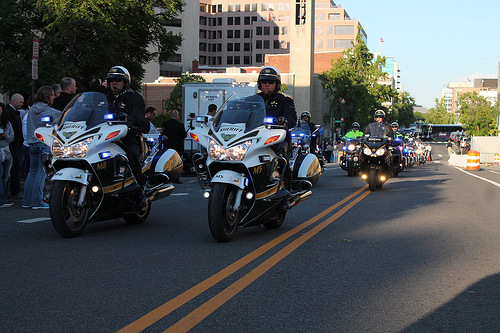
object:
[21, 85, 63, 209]
people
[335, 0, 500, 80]
sky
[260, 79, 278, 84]
eyeglasses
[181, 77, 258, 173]
ambulance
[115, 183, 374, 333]
line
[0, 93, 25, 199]
person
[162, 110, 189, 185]
person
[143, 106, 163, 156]
person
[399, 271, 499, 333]
shadow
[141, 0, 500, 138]
buildings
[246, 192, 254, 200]
light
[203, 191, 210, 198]
light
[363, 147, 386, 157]
light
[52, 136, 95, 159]
light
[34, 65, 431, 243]
motorcycle parade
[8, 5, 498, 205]
background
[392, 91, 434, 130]
trees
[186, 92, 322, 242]
bike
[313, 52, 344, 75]
red bricks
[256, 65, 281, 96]
helmet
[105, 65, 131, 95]
helmet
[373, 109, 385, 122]
helmet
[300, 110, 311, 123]
helmet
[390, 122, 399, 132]
helmet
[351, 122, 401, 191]
bike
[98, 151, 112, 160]
light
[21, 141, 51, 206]
blue jeans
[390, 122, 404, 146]
officer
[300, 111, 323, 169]
officer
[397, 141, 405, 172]
motorcycle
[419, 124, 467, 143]
bus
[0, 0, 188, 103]
tree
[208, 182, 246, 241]
wheel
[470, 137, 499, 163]
wall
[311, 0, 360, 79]
wall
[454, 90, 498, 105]
wall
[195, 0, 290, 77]
wall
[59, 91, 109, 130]
windshield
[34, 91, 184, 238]
bike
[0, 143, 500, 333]
street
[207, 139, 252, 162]
motorcycle headlights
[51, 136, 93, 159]
motorcycle headlights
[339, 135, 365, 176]
motorcycle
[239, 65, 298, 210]
officer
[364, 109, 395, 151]
officer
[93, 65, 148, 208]
officer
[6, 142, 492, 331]
ground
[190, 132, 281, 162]
lights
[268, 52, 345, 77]
wall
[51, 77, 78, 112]
people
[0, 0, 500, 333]
cityscape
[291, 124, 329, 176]
motorcycle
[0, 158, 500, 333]
road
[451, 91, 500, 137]
tree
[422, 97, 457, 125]
tree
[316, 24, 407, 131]
tree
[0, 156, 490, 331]
roadside